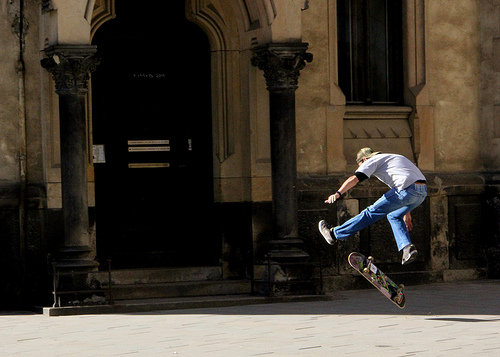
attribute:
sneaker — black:
[314, 217, 336, 243]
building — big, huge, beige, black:
[0, 2, 499, 315]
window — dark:
[328, 13, 428, 98]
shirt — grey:
[356, 153, 438, 191]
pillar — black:
[239, 30, 349, 153]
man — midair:
[307, 142, 429, 309]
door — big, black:
[95, 0, 216, 267]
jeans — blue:
[332, 183, 425, 248]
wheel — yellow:
[366, 256, 374, 261]